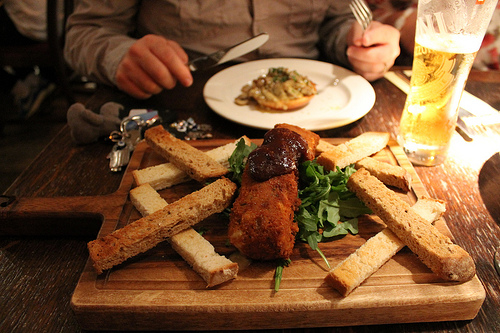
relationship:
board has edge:
[118, 123, 470, 302] [92, 211, 135, 322]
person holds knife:
[33, 6, 403, 74] [180, 31, 259, 73]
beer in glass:
[393, 17, 445, 148] [398, 2, 484, 147]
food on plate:
[249, 74, 305, 108] [201, 54, 379, 127]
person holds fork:
[33, 6, 403, 74] [348, 5, 379, 34]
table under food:
[14, 48, 253, 330] [249, 74, 305, 108]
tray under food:
[118, 123, 470, 302] [249, 74, 305, 108]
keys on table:
[100, 102, 227, 174] [14, 48, 253, 330]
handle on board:
[0, 194, 114, 235] [118, 123, 470, 302]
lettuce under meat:
[287, 155, 346, 243] [240, 124, 298, 245]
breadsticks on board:
[98, 122, 258, 300] [118, 123, 470, 302]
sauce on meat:
[236, 135, 307, 179] [240, 124, 298, 245]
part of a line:
[135, 274, 170, 289] [2, 148, 66, 199]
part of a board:
[389, 270, 419, 303] [118, 123, 470, 302]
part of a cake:
[256, 205, 287, 242] [242, 117, 305, 254]